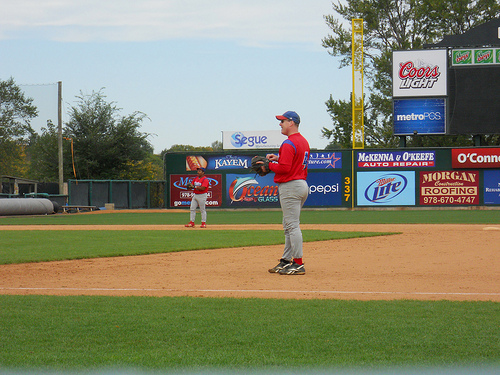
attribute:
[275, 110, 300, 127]
cap — red , blue 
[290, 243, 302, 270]
socks — red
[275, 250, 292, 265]
socks — red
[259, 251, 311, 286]
shoes — black, white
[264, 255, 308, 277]
shoes — black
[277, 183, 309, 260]
pants — tan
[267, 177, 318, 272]
grey pants — grey 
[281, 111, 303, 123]
cap — blue